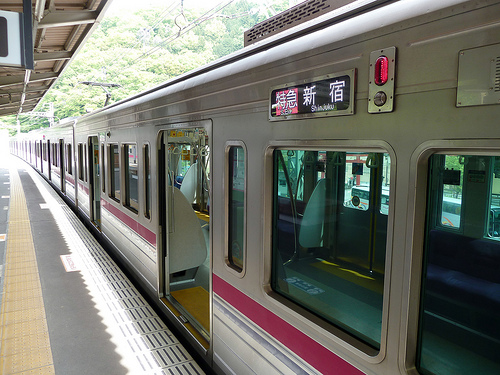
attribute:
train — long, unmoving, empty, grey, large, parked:
[6, 2, 499, 373]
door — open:
[155, 117, 222, 368]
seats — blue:
[424, 228, 500, 344]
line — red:
[212, 271, 366, 374]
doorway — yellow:
[168, 284, 220, 349]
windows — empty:
[257, 132, 402, 366]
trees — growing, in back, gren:
[2, 2, 302, 140]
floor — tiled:
[3, 151, 204, 372]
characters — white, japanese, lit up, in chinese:
[272, 89, 299, 117]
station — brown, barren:
[0, 0, 212, 373]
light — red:
[370, 52, 393, 87]